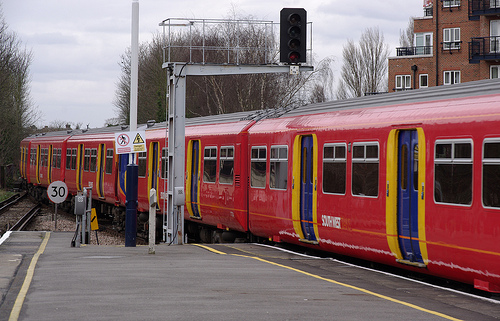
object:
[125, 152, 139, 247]
pole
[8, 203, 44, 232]
rails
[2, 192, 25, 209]
rails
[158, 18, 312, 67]
rails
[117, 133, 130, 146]
sign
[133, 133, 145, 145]
sign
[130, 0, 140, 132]
pole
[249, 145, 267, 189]
windows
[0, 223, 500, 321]
platform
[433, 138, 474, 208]
windows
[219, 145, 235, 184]
windows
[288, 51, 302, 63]
light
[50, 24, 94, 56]
sky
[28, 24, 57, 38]
cloud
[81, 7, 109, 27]
cloud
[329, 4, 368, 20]
cloud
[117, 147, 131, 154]
signs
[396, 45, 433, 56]
balcony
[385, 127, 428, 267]
door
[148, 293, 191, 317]
concrete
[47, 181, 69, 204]
sign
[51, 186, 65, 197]
30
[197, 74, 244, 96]
tree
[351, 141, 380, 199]
windows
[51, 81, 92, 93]
sky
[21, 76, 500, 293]
train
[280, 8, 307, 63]
chairsignal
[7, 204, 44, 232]
track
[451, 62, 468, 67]
brick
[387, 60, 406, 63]
brick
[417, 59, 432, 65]
brick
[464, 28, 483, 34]
brick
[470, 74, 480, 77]
brick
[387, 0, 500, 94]
building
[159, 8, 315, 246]
metal light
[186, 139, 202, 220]
door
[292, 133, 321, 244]
door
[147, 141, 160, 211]
door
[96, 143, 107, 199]
door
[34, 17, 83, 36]
white clouds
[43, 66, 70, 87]
clouds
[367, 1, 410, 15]
sky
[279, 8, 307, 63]
signal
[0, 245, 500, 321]
waiting area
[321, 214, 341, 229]
lettering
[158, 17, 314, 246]
structure